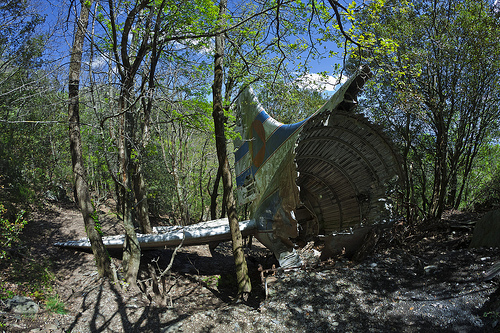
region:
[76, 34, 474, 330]
an airplane in the woods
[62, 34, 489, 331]
an airplane tail in the woods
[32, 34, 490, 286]
a broken airplane in the woods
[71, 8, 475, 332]
a plane in the woods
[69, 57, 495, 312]
a plane tail in the woods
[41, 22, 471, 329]
a broken plane in the woods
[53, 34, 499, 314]
a plane crashed in the woods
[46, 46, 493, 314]
an airplane crashed in the woods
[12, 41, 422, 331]
the tail of an airplane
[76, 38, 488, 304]
the tail of a plane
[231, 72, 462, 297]
plane crashed in woods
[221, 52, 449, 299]
remnants of a plane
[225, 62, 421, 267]
half of a plane in the woods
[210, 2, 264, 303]
tall brown tree trunk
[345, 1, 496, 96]
green leaves on a tree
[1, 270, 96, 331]
leaves on the ground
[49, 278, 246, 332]
shadow of a tree on the ground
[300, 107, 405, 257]
inside of a plane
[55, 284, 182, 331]
brown dirt on the ground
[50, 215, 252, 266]
wing of a plane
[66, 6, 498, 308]
a plane in the wodds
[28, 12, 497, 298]
the tail of an airplane in the woods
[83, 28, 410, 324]
the tail of a plane in the woods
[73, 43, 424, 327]
an airplane tail crashed in the woods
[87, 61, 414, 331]
a plane tail crashed in the woods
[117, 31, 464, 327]
an airplane tale crashed in the woods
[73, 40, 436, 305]
the plane reck of he plane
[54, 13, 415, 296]
it is blue and white in colour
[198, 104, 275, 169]
it has a drawing on the body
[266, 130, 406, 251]
it is circular in shape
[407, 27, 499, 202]
the tree has thin branches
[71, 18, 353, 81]
the sky is blue with some clouds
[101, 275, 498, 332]
the ground has no leaves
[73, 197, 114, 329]
creepers on a tree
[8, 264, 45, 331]
a rock is grey in colour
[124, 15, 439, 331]
the tail is between trees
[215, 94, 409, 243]
A piece of an airplane in the woods.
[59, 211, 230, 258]
Wing of the plane.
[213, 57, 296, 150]
Tail of the plane.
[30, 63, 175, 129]
Branches on the tree.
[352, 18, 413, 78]
Green leaves on the tree.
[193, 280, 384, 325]
Dirt on the ground.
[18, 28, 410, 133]
Trees in the wood.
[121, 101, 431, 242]
Crash part of an airplane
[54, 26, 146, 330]
The tree has long trunks.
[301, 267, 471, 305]
Rocks on the ground.